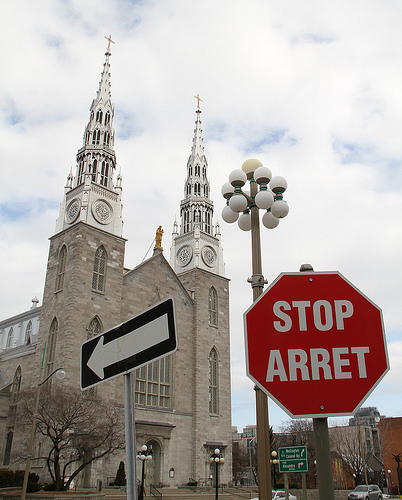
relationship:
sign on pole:
[79, 295, 179, 389] [305, 418, 339, 498]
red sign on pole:
[242, 268, 391, 420] [300, 414, 344, 498]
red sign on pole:
[242, 268, 391, 420] [278, 476, 293, 498]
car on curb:
[346, 483, 381, 499] [228, 493, 258, 498]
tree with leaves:
[16, 381, 139, 472] [24, 391, 111, 458]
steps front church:
[57, 487, 259, 499] [2, 20, 252, 498]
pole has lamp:
[104, 376, 159, 498] [54, 368, 67, 383]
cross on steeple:
[103, 33, 116, 52] [103, 56, 111, 103]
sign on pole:
[70, 281, 180, 367] [124, 380, 145, 495]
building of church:
[36, 252, 230, 497] [0, 79, 233, 488]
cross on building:
[103, 33, 116, 52] [1, 32, 233, 489]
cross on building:
[192, 93, 203, 108] [1, 32, 233, 489]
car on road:
[346, 483, 381, 498] [20, 492, 401, 500]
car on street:
[271, 489, 284, 498] [255, 486, 301, 498]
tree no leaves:
[3, 380, 129, 491] [32, 395, 122, 460]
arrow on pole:
[86, 310, 169, 382] [114, 375, 148, 497]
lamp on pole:
[35, 363, 69, 400] [251, 208, 280, 498]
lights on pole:
[216, 155, 294, 234] [249, 230, 275, 496]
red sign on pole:
[242, 268, 391, 419] [317, 420, 328, 498]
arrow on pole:
[86, 315, 169, 378] [122, 373, 150, 496]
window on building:
[122, 343, 176, 418] [0, 244, 236, 491]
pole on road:
[209, 443, 227, 494] [20, 420, 401, 496]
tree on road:
[3, 380, 129, 491] [272, 493, 400, 498]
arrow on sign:
[86, 310, 169, 382] [79, 291, 180, 395]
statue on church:
[153, 224, 163, 251] [1, 31, 235, 491]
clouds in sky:
[251, 23, 390, 151] [245, 26, 401, 154]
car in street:
[346, 483, 381, 499] [188, 474, 391, 494]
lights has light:
[241, 155, 263, 177] [262, 210, 282, 231]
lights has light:
[241, 155, 263, 177] [254, 188, 276, 212]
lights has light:
[241, 155, 263, 177] [234, 214, 254, 230]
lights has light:
[241, 155, 263, 177] [266, 176, 289, 190]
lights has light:
[241, 155, 263, 177] [252, 162, 270, 181]